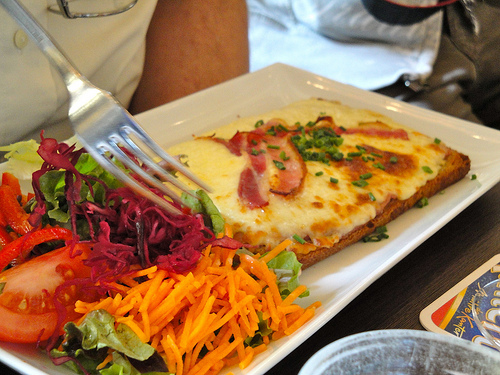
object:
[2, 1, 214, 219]
fork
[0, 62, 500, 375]
plate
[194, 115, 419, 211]
bacon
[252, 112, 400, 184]
chives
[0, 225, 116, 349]
tomato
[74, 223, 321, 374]
carrots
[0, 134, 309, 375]
lettuce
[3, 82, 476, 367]
lunch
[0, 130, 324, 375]
salad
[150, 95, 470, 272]
bread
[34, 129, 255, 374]
cabbage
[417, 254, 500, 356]
coaster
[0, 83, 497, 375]
table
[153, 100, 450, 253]
cheese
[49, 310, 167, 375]
lettuce leaf